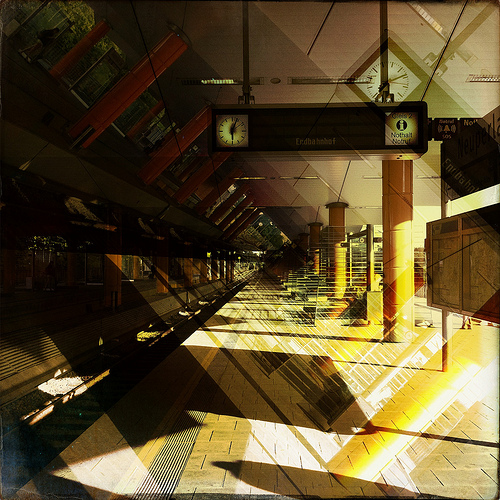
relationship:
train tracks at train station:
[36, 319, 155, 409] [25, 28, 490, 498]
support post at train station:
[356, 218, 376, 299] [25, 28, 490, 498]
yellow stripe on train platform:
[139, 350, 204, 488] [142, 270, 496, 484]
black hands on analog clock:
[223, 112, 251, 150] [215, 114, 249, 148]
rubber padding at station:
[155, 325, 216, 495] [1, 76, 500, 500]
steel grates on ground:
[135, 316, 242, 492] [68, 294, 462, 484]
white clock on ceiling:
[349, 40, 428, 121] [179, 9, 498, 159]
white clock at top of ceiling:
[349, 40, 428, 121] [136, 5, 495, 125]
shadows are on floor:
[147, 335, 367, 495] [85, 275, 498, 484]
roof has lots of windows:
[15, 2, 236, 291] [25, 0, 223, 215]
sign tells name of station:
[201, 95, 433, 161] [11, 14, 491, 493]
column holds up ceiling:
[378, 154, 416, 346] [207, 3, 497, 212]